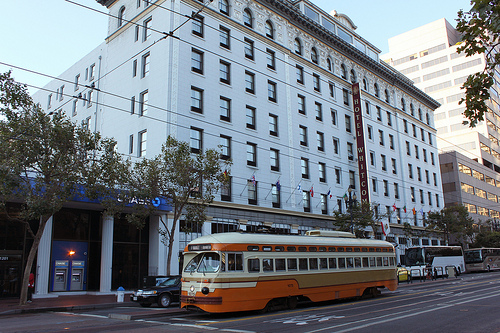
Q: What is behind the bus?
A: A hotel.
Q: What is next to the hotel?
A: A bank.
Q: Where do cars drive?
A: The street.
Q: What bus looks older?
A: The orange bus.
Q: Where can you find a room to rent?
A: The hotel.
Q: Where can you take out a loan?
A: The bank.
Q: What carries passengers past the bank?
A: An orange bus.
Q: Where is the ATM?
A: The bank.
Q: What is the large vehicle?
A: Bus.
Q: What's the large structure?
A: Building.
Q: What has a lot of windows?
A: Building.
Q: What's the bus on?
A: Road.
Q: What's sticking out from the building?
A: Flags.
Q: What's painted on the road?
A: Lines.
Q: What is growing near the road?
A: Trees.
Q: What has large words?
A: Building sign.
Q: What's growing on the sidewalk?
A: Trees.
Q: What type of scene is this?
A: Outdoor.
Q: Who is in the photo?
A: No one.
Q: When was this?
A: Daytime.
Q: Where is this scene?
A: Street.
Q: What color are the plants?
A: Green.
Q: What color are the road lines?
A: White.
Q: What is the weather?
A: Sunny.